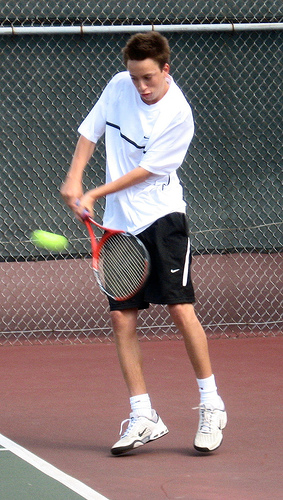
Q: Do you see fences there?
A: Yes, there is a fence.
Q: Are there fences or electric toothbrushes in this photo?
A: Yes, there is a fence.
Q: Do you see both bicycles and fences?
A: No, there is a fence but no bikes.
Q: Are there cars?
A: No, there are no cars.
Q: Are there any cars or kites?
A: No, there are no cars or kites.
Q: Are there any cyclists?
A: No, there are no cyclists.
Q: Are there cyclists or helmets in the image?
A: No, there are no cyclists or helmets.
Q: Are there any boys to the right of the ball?
A: Yes, there is a boy to the right of the ball.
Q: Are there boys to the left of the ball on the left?
A: No, the boy is to the right of the ball.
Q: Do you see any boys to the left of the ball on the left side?
A: No, the boy is to the right of the ball.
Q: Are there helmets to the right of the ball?
A: No, there is a boy to the right of the ball.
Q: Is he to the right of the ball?
A: Yes, the boy is to the right of the ball.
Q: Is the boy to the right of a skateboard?
A: No, the boy is to the right of the ball.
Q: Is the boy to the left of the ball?
A: No, the boy is to the right of the ball.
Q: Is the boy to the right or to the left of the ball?
A: The boy is to the right of the ball.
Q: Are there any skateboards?
A: No, there are no skateboards.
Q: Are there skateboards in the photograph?
A: No, there are no skateboards.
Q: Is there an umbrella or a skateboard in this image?
A: No, there are no skateboards or umbrellas.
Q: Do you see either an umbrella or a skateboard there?
A: No, there are no skateboards or umbrellas.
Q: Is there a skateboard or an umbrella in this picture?
A: No, there are no skateboards or umbrellas.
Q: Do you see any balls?
A: Yes, there is a ball.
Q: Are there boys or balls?
A: Yes, there is a ball.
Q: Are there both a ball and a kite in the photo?
A: No, there is a ball but no kites.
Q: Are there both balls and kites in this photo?
A: No, there is a ball but no kites.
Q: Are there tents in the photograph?
A: No, there are no tents.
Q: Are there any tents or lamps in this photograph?
A: No, there are no tents or lamps.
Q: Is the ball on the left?
A: Yes, the ball is on the left of the image.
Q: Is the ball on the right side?
A: No, the ball is on the left of the image.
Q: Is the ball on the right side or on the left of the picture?
A: The ball is on the left of the image.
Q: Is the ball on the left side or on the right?
A: The ball is on the left of the image.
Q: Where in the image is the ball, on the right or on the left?
A: The ball is on the left of the image.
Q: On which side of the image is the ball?
A: The ball is on the left of the image.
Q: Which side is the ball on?
A: The ball is on the left of the image.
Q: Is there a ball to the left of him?
A: Yes, there is a ball to the left of the boy.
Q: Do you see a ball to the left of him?
A: Yes, there is a ball to the left of the boy.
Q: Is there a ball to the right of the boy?
A: No, the ball is to the left of the boy.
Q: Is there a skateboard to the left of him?
A: No, there is a ball to the left of the boy.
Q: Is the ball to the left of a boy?
A: Yes, the ball is to the left of a boy.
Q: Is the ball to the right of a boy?
A: No, the ball is to the left of a boy.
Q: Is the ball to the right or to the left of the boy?
A: The ball is to the left of the boy.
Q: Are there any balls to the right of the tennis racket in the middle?
A: No, the ball is to the left of the racket.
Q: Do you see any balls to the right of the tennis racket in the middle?
A: No, the ball is to the left of the racket.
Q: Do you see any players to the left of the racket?
A: No, there is a ball to the left of the racket.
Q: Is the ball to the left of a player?
A: No, the ball is to the left of the racket.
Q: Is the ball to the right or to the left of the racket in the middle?
A: The ball is to the left of the racket.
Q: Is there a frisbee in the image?
A: No, there are no frisbees.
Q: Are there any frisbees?
A: No, there are no frisbees.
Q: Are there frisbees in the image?
A: No, there are no frisbees.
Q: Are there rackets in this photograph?
A: Yes, there is a racket.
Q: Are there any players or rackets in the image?
A: Yes, there is a racket.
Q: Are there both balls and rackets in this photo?
A: Yes, there are both a racket and a ball.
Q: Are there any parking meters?
A: No, there are no parking meters.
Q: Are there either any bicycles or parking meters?
A: No, there are no parking meters or bicycles.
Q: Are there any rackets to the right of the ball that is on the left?
A: Yes, there is a racket to the right of the ball.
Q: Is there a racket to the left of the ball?
A: No, the racket is to the right of the ball.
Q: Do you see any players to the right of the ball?
A: No, there is a racket to the right of the ball.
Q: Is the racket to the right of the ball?
A: Yes, the racket is to the right of the ball.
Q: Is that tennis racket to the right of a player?
A: No, the tennis racket is to the right of the ball.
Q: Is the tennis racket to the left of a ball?
A: No, the tennis racket is to the right of a ball.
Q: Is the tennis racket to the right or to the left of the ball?
A: The tennis racket is to the right of the ball.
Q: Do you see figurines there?
A: No, there are no figurines.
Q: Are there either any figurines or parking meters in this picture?
A: No, there are no figurines or parking meters.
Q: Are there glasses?
A: No, there are no glasses.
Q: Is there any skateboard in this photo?
A: No, there are no skateboards.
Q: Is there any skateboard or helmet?
A: No, there are no skateboards or helmets.